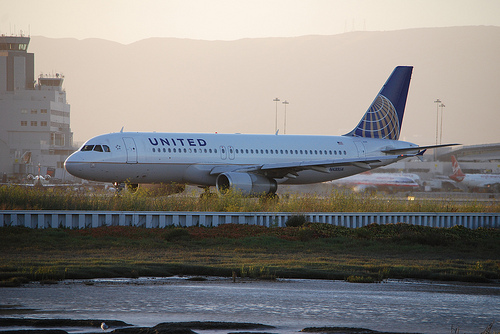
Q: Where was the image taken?
A: It was taken at the airport.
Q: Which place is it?
A: It is an airport.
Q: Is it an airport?
A: Yes, it is an airport.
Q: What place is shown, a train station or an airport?
A: It is an airport.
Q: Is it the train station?
A: No, it is the airport.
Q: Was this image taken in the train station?
A: No, the picture was taken in the airport.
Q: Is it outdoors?
A: Yes, it is outdoors.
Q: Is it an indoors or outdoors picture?
A: It is outdoors.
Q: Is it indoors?
A: No, it is outdoors.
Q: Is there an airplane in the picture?
A: Yes, there is an airplane.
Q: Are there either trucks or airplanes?
A: Yes, there is an airplane.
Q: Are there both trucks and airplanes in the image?
A: No, there is an airplane but no trucks.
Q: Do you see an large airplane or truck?
A: Yes, there is a large airplane.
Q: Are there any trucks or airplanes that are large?
A: Yes, the airplane is large.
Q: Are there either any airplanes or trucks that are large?
A: Yes, the airplane is large.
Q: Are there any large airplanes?
A: Yes, there is a large airplane.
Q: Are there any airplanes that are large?
A: Yes, there is an airplane that is large.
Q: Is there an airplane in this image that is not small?
A: Yes, there is a large airplane.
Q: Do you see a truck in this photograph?
A: No, there are no trucks.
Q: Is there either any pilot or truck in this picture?
A: No, there are no trucks or pilots.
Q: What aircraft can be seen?
A: The aircraft is an airplane.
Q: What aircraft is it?
A: The aircraft is an airplane.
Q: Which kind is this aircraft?
A: This is an airplane.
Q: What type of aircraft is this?
A: This is an airplane.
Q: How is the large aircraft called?
A: The aircraft is an airplane.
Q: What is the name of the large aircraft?
A: The aircraft is an airplane.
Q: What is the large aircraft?
A: The aircraft is an airplane.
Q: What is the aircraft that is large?
A: The aircraft is an airplane.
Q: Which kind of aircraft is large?
A: The aircraft is an airplane.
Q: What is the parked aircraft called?
A: The aircraft is an airplane.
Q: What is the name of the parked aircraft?
A: The aircraft is an airplane.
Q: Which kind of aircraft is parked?
A: The aircraft is an airplane.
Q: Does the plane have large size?
A: Yes, the plane is large.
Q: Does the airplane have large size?
A: Yes, the airplane is large.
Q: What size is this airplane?
A: The airplane is large.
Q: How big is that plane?
A: The plane is large.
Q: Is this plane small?
A: No, the plane is large.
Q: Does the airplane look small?
A: No, the airplane is large.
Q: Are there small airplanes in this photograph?
A: No, there is an airplane but it is large.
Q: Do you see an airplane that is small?
A: No, there is an airplane but it is large.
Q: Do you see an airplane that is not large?
A: No, there is an airplane but it is large.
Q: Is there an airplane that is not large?
A: No, there is an airplane but it is large.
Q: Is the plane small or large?
A: The plane is large.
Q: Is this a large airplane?
A: Yes, this is a large airplane.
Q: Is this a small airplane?
A: No, this is a large airplane.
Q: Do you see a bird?
A: No, there are no birds.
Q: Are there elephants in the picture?
A: No, there are no elephants.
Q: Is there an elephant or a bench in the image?
A: No, there are no elephants or benches.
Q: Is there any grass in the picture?
A: Yes, there is grass.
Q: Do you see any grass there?
A: Yes, there is grass.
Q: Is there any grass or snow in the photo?
A: Yes, there is grass.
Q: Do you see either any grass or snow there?
A: Yes, there is grass.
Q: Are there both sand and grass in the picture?
A: No, there is grass but no sand.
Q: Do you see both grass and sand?
A: No, there is grass but no sand.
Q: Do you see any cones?
A: No, there are no cones.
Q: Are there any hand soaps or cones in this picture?
A: No, there are no cones or hand soaps.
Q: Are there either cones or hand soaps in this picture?
A: No, there are no cones or hand soaps.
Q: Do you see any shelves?
A: No, there are no shelves.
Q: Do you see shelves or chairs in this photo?
A: No, there are no shelves or chairs.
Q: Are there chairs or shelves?
A: No, there are no shelves or chairs.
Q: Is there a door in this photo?
A: Yes, there is a door.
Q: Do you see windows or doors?
A: Yes, there is a door.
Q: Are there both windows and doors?
A: Yes, there are both a door and a window.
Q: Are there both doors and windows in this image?
A: Yes, there are both a door and a window.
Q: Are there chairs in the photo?
A: No, there are no chairs.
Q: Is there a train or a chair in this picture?
A: No, there are no chairs or trains.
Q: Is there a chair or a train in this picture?
A: No, there are no chairs or trains.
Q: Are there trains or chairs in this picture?
A: No, there are no chairs or trains.